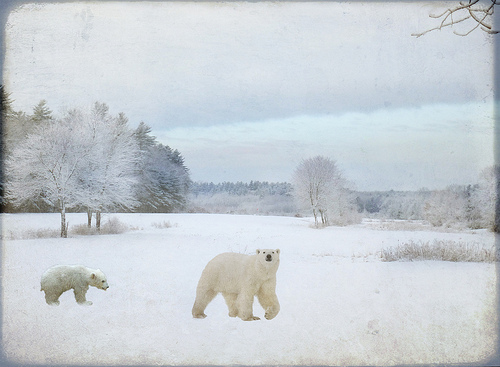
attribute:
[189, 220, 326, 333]
bear — polar, eye, walking, young, looking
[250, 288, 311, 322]
paw — lifted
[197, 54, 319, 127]
sky — clouds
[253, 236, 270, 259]
eye — black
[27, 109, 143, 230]
tree — white, frozen, frosted, covered